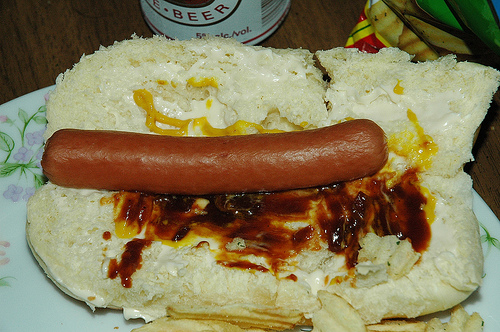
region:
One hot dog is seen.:
[38, 127, 374, 179]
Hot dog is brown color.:
[71, 144, 333, 183]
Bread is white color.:
[46, 208, 116, 288]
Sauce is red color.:
[141, 208, 367, 242]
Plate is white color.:
[15, 277, 47, 314]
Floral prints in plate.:
[5, 116, 36, 188]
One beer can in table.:
[143, 1, 273, 43]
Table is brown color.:
[22, 19, 97, 64]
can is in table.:
[76, 5, 203, 49]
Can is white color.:
[126, 9, 287, 56]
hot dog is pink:
[21, 103, 413, 205]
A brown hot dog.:
[37, 131, 409, 188]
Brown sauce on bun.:
[126, 179, 460, 255]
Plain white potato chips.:
[142, 303, 478, 330]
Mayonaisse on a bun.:
[268, 260, 390, 297]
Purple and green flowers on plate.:
[1, 94, 41, 249]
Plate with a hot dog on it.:
[16, 98, 491, 294]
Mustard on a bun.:
[79, 88, 241, 135]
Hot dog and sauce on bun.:
[105, 100, 488, 285]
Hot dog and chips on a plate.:
[71, 149, 425, 324]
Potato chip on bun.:
[301, 223, 446, 293]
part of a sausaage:
[187, 159, 296, 178]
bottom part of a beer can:
[260, 22, 270, 39]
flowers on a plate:
[21, 120, 33, 153]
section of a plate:
[21, 266, 39, 321]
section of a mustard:
[145, 106, 157, 124]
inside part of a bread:
[163, 270, 185, 281]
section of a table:
[21, 24, 51, 66]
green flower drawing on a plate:
[24, 115, 41, 123]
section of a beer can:
[166, 10, 253, 27]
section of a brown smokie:
[70, 152, 238, 166]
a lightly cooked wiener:
[36, 106, 399, 196]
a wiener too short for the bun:
[25, 32, 496, 323]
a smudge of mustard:
[128, 85, 435, 133]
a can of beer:
[139, 1, 289, 44]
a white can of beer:
[139, 0, 289, 48]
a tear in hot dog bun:
[288, 40, 358, 125]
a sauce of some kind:
[103, 160, 429, 284]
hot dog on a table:
[1, 0, 498, 314]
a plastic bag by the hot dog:
[343, 0, 439, 60]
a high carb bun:
[24, 36, 496, 330]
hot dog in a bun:
[21, 93, 408, 236]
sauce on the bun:
[127, 186, 412, 266]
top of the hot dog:
[8, 88, 141, 231]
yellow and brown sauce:
[375, 95, 462, 257]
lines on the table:
[6, 10, 98, 62]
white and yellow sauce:
[122, 69, 258, 141]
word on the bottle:
[171, 2, 235, 33]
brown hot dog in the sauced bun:
[23, 92, 402, 217]